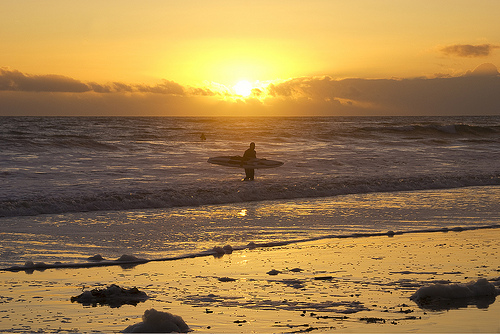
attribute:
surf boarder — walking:
[210, 125, 303, 177]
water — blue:
[381, 138, 461, 193]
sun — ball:
[233, 81, 255, 98]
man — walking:
[212, 88, 292, 219]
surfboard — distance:
[207, 149, 283, 185]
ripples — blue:
[2, 180, 497, 223]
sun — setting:
[216, 66, 267, 96]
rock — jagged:
[58, 277, 157, 309]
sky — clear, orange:
[285, 31, 427, 91]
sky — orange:
[82, 29, 409, 114]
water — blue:
[0, 116, 497, 271]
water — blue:
[26, 109, 474, 274]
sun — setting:
[18, 47, 458, 118]